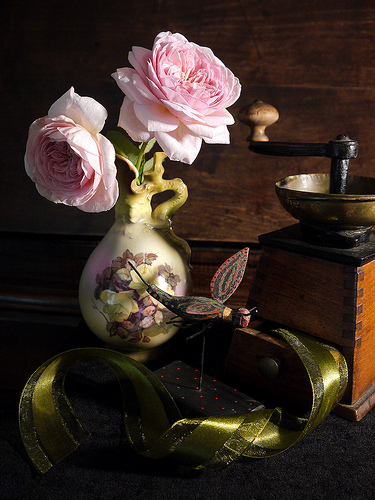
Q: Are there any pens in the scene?
A: No, there are no pens.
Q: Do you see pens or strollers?
A: No, there are no pens or strollers.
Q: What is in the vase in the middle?
A: The plant is in the vase.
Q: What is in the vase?
A: The plant is in the vase.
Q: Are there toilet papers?
A: No, there are no toilet papers.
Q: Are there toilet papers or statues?
A: No, there are no toilet papers or statues.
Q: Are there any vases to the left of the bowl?
A: Yes, there is a vase to the left of the bowl.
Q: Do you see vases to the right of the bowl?
A: No, the vase is to the left of the bowl.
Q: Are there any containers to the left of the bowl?
A: No, there is a vase to the left of the bowl.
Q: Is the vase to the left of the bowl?
A: Yes, the vase is to the left of the bowl.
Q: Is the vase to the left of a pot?
A: No, the vase is to the left of the bowl.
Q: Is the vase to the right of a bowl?
A: No, the vase is to the left of a bowl.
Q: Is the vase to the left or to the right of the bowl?
A: The vase is to the left of the bowl.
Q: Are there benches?
A: No, there are no benches.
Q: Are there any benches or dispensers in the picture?
A: No, there are no benches or dispensers.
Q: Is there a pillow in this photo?
A: No, there are no pillows.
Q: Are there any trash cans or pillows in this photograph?
A: No, there are no pillows or trash cans.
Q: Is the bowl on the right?
A: Yes, the bowl is on the right of the image.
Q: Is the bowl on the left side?
A: No, the bowl is on the right of the image.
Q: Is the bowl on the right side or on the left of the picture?
A: The bowl is on the right of the image.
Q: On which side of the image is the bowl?
A: The bowl is on the right of the image.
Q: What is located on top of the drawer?
A: The bowl is on top of the drawer.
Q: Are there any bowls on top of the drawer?
A: Yes, there is a bowl on top of the drawer.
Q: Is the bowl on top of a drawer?
A: Yes, the bowl is on top of a drawer.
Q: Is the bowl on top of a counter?
A: No, the bowl is on top of a drawer.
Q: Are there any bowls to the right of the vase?
A: Yes, there is a bowl to the right of the vase.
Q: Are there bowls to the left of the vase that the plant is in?
A: No, the bowl is to the right of the vase.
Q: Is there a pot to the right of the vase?
A: No, there is a bowl to the right of the vase.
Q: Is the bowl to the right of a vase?
A: Yes, the bowl is to the right of a vase.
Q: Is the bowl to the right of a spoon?
A: No, the bowl is to the right of a vase.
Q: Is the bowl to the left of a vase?
A: No, the bowl is to the right of a vase.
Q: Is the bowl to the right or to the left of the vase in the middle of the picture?
A: The bowl is to the right of the vase.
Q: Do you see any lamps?
A: No, there are no lamps.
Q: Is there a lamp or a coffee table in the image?
A: No, there are no lamps or coffee tables.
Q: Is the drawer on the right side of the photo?
A: Yes, the drawer is on the right of the image.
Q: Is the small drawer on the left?
A: No, the drawer is on the right of the image.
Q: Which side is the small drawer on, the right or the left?
A: The drawer is on the right of the image.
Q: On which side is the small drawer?
A: The drawer is on the right of the image.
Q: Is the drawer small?
A: Yes, the drawer is small.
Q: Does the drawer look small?
A: Yes, the drawer is small.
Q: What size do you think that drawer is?
A: The drawer is small.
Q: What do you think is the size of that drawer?
A: The drawer is small.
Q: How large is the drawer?
A: The drawer is small.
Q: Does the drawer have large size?
A: No, the drawer is small.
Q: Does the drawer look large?
A: No, the drawer is small.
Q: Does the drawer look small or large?
A: The drawer is small.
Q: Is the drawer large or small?
A: The drawer is small.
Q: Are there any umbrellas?
A: No, there are no umbrellas.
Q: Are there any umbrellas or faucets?
A: No, there are no umbrellas or faucets.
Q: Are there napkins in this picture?
A: No, there are no napkins.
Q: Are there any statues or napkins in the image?
A: No, there are no napkins or statues.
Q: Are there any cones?
A: No, there are no cones.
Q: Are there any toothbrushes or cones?
A: No, there are no cones or toothbrushes.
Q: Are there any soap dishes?
A: No, there are no soap dishes.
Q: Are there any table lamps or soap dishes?
A: No, there are no soap dishes or table lamps.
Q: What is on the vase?
A: The decoration is on the vase.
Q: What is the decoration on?
A: The decoration is on the vase.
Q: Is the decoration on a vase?
A: Yes, the decoration is on a vase.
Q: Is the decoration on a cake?
A: No, the decoration is on a vase.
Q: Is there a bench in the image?
A: No, there are no benches.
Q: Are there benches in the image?
A: No, there are no benches.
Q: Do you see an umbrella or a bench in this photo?
A: No, there are no benches or umbrellas.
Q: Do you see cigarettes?
A: No, there are no cigarettes.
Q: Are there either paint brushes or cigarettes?
A: No, there are no cigarettes or paint brushes.